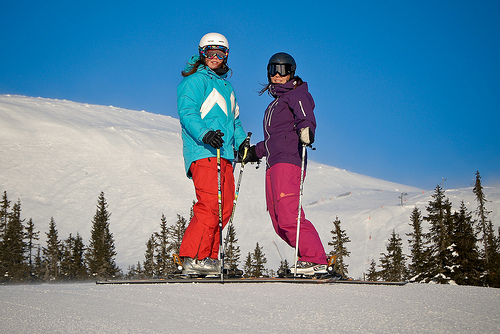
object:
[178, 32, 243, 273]
woman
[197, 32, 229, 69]
helmet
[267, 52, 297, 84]
helmet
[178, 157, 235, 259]
pant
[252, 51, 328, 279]
women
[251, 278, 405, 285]
ski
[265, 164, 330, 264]
pant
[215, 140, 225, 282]
pole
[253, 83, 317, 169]
jacket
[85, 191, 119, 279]
tree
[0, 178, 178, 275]
distance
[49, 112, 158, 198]
snow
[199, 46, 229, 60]
goggle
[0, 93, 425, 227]
hill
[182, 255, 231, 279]
boot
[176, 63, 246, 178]
coat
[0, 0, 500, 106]
sky